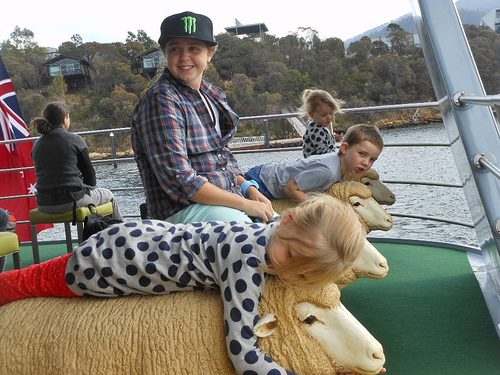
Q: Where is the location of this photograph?
A: A boat.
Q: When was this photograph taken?
A: Early evening.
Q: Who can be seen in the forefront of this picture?
A: Kids.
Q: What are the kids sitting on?
A: Sheep.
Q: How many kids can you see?
A: 4.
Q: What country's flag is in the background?
A: Britain's.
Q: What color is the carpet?
A: Green.